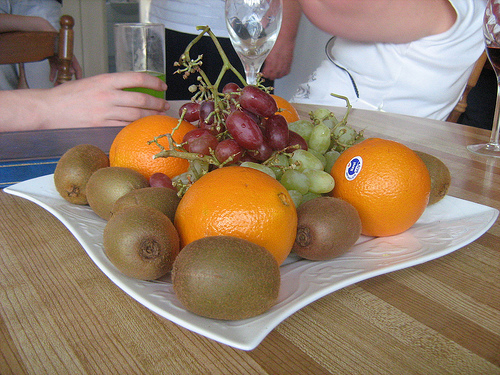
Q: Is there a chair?
A: Yes, there is a chair.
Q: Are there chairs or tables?
A: Yes, there is a chair.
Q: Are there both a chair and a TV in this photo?
A: No, there is a chair but no televisions.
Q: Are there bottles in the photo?
A: No, there are no bottles.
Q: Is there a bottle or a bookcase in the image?
A: No, there are no bottles or bookcases.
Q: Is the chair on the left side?
A: Yes, the chair is on the left of the image.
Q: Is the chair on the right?
A: No, the chair is on the left of the image.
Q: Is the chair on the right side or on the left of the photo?
A: The chair is on the left of the image.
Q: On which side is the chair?
A: The chair is on the left of the image.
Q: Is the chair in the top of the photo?
A: Yes, the chair is in the top of the image.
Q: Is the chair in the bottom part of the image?
A: No, the chair is in the top of the image.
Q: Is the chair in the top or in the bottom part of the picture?
A: The chair is in the top of the image.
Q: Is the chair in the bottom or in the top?
A: The chair is in the top of the image.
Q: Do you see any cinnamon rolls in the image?
A: No, there are no cinnamon rolls.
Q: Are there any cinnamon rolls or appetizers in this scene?
A: No, there are no cinnamon rolls or appetizers.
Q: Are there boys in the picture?
A: No, there are no boys.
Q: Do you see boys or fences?
A: No, there are no boys or fences.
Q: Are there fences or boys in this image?
A: No, there are no boys or fences.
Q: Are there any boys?
A: No, there are no boys.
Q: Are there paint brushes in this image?
A: No, there are no paint brushes.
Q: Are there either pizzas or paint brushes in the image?
A: No, there are no paint brushes or pizzas.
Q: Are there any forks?
A: No, there are no forks.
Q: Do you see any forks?
A: No, there are no forks.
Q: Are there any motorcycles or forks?
A: No, there are no forks or motorcycles.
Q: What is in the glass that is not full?
A: The liquid is in the glass.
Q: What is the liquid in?
A: The liquid is in the glass.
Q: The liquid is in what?
A: The liquid is in the glass.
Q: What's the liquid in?
A: The liquid is in the glass.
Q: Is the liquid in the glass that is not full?
A: Yes, the liquid is in the glass.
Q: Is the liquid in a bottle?
A: No, the liquid is in the glass.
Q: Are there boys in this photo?
A: No, there are no boys.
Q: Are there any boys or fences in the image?
A: No, there are no boys or fences.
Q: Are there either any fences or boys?
A: No, there are no boys or fences.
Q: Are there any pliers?
A: No, there are no pliers.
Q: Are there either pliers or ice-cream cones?
A: No, there are no pliers or ice-cream cones.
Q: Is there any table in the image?
A: Yes, there is a table.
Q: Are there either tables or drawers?
A: Yes, there is a table.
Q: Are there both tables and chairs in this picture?
A: Yes, there are both a table and a chair.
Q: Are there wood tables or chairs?
A: Yes, there is a wood table.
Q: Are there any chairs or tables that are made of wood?
A: Yes, the table is made of wood.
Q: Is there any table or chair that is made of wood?
A: Yes, the table is made of wood.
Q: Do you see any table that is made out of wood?
A: Yes, there is a table that is made of wood.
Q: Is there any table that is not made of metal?
A: Yes, there is a table that is made of wood.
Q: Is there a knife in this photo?
A: No, there are no knives.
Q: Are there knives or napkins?
A: No, there are no knives or napkins.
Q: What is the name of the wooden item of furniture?
A: The piece of furniture is a table.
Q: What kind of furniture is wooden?
A: The furniture is a table.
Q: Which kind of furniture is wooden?
A: The furniture is a table.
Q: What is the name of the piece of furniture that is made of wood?
A: The piece of furniture is a table.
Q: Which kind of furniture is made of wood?
A: The furniture is a table.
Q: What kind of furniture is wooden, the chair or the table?
A: The table is wooden.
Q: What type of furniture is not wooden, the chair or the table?
A: The chair is not wooden.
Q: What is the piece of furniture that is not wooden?
A: The piece of furniture is a chair.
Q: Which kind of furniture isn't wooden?
A: The furniture is a chair.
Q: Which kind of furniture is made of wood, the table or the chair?
A: The table is made of wood.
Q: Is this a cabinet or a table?
A: This is a table.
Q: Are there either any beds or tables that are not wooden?
A: No, there is a table but it is wooden.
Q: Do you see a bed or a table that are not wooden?
A: No, there is a table but it is wooden.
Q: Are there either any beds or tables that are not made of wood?
A: No, there is a table but it is made of wood.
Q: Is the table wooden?
A: Yes, the table is wooden.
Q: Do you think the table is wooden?
A: Yes, the table is wooden.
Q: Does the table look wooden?
A: Yes, the table is wooden.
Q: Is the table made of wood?
A: Yes, the table is made of wood.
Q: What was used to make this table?
A: The table is made of wood.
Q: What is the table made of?
A: The table is made of wood.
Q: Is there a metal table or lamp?
A: No, there is a table but it is wooden.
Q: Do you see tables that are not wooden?
A: No, there is a table but it is wooden.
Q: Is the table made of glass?
A: No, the table is made of wood.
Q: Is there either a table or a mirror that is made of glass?
A: No, there is a table but it is made of wood.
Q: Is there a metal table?
A: No, there is a table but it is made of wood.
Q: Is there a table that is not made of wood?
A: No, there is a table but it is made of wood.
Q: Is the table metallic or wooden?
A: The table is wooden.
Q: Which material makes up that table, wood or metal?
A: The table is made of wood.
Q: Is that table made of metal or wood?
A: The table is made of wood.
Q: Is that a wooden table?
A: Yes, that is a wooden table.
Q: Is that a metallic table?
A: No, that is a wooden table.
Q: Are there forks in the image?
A: No, there are no forks.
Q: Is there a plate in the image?
A: Yes, there is a plate.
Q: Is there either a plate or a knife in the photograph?
A: Yes, there is a plate.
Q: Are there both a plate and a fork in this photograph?
A: No, there is a plate but no forks.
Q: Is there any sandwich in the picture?
A: No, there are no sandwiches.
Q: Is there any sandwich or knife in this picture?
A: No, there are no sandwiches or knives.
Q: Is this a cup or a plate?
A: This is a plate.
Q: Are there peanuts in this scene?
A: No, there are no peanuts.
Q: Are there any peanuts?
A: No, there are no peanuts.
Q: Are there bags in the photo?
A: No, there are no bags.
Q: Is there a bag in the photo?
A: No, there are no bags.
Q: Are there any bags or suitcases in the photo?
A: No, there are no bags or suitcases.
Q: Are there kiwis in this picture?
A: Yes, there is a kiwi.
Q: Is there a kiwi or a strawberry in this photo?
A: Yes, there is a kiwi.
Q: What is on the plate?
A: The kiwi is on the plate.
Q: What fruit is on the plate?
A: The fruit is a kiwi.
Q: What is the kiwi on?
A: The kiwi is on the plate.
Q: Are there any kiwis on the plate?
A: Yes, there is a kiwi on the plate.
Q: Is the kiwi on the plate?
A: Yes, the kiwi is on the plate.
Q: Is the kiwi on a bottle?
A: No, the kiwi is on the plate.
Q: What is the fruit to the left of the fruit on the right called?
A: The fruit is a kiwi.